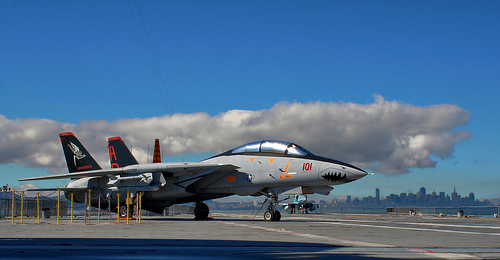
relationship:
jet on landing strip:
[16, 131, 378, 221] [0, 212, 498, 258]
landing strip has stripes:
[0, 212, 498, 258] [204, 211, 499, 251]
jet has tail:
[16, 131, 378, 221] [56, 129, 140, 204]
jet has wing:
[16, 131, 378, 221] [17, 160, 229, 183]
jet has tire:
[16, 131, 378, 221] [193, 200, 210, 219]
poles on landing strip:
[8, 188, 141, 227] [0, 212, 498, 258]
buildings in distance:
[309, 186, 492, 209] [0, 168, 498, 215]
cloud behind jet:
[2, 93, 475, 177] [16, 131, 378, 221]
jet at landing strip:
[16, 131, 378, 221] [0, 212, 498, 258]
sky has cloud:
[0, 2, 498, 202] [2, 93, 475, 177]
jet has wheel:
[16, 131, 378, 221] [192, 203, 208, 216]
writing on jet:
[302, 161, 314, 173] [16, 131, 378, 221]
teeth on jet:
[319, 163, 364, 185] [16, 131, 378, 221]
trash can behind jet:
[43, 204, 52, 219] [16, 131, 378, 221]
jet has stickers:
[16, 131, 378, 221] [227, 157, 295, 181]